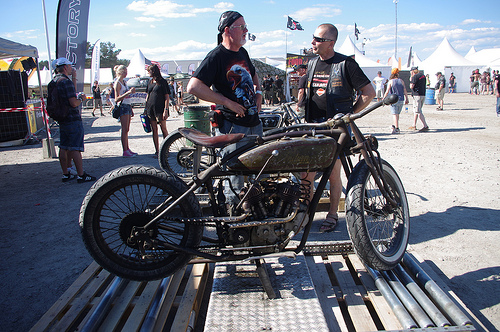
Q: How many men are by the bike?
A: Two.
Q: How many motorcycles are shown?
A: One.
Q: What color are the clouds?
A: White.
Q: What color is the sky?
A: Blue.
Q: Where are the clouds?
A: In sky.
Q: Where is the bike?
A: On platform.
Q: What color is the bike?
A: Black.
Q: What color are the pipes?
A: Silver.